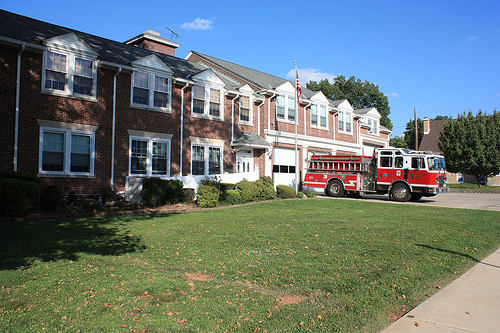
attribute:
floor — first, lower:
[366, 133, 429, 160]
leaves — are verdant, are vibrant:
[444, 110, 499, 180]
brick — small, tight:
[33, 97, 65, 120]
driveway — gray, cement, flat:
[315, 192, 499, 217]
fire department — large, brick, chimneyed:
[0, 8, 395, 208]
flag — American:
[284, 57, 309, 104]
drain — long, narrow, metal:
[108, 73, 117, 196]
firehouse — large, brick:
[181, 58, 408, 197]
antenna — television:
[160, 26, 185, 53]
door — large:
[271, 147, 300, 193]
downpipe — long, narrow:
[110, 68, 117, 188]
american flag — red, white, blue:
[287, 55, 310, 107]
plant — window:
[289, 59, 306, 111]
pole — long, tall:
[269, 61, 350, 202]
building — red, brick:
[46, 26, 491, 237]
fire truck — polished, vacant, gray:
[296, 143, 449, 203]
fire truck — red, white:
[274, 114, 466, 221]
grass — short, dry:
[183, 214, 473, 266]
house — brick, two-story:
[0, 7, 395, 204]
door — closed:
[272, 146, 299, 195]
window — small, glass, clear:
[287, 164, 296, 173]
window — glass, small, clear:
[278, 164, 288, 174]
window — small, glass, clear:
[270, 163, 280, 171]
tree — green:
[443, 116, 498, 176]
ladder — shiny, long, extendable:
[309, 146, 381, 183]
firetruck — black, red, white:
[285, 124, 478, 216]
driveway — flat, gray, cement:
[436, 174, 495, 232]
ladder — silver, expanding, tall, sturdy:
[307, 157, 368, 177]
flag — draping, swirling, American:
[287, 64, 301, 111]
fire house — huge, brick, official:
[2, 0, 394, 195]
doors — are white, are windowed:
[224, 145, 271, 182]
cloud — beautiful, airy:
[180, 16, 218, 36]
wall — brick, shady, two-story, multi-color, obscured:
[100, 70, 130, 138]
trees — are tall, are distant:
[411, 111, 483, 184]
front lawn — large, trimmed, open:
[1, 192, 456, 316]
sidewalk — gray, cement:
[418, 287, 483, 322]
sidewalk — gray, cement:
[438, 189, 484, 209]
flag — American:
[291, 60, 303, 109]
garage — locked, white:
[268, 145, 303, 195]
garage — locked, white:
[307, 145, 327, 168]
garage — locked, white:
[334, 146, 363, 159]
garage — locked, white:
[363, 139, 392, 160]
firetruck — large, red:
[303, 147, 453, 199]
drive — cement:
[308, 188, 484, 208]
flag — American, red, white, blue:
[286, 56, 309, 106]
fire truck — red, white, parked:
[305, 153, 450, 195]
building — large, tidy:
[5, 14, 425, 205]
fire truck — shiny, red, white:
[302, 150, 462, 200]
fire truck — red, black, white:
[300, 148, 453, 200]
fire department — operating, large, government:
[9, 2, 462, 284]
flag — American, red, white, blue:
[289, 60, 305, 102]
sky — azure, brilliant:
[172, 8, 445, 68]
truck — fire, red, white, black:
[297, 149, 446, 199]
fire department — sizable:
[6, 10, 434, 303]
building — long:
[7, 77, 384, 204]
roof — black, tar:
[5, 37, 391, 83]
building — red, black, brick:
[7, 97, 425, 222]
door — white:
[234, 149, 256, 189]